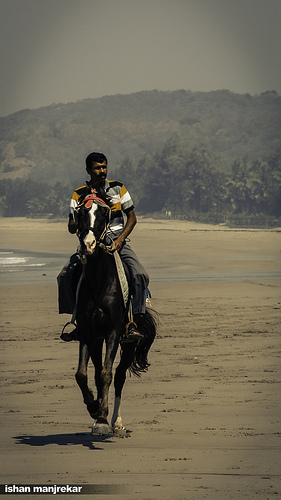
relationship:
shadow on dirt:
[11, 426, 134, 450] [179, 281, 226, 354]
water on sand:
[10, 250, 45, 270] [0, 248, 48, 266]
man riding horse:
[56, 152, 151, 343] [64, 190, 165, 311]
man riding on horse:
[60, 150, 148, 339] [67, 177, 166, 440]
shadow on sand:
[9, 428, 132, 449] [0, 218, 280, 499]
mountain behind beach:
[0, 88, 281, 229] [0, 217, 280, 499]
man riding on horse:
[60, 150, 148, 339] [72, 178, 155, 436]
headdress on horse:
[76, 193, 110, 213] [55, 189, 156, 439]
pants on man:
[102, 230, 151, 314] [51, 155, 160, 350]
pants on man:
[46, 243, 77, 324] [51, 155, 160, 350]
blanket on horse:
[108, 238, 131, 308] [50, 196, 163, 442]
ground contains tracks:
[175, 40, 220, 62] [112, 360, 225, 439]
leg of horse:
[94, 319, 125, 430] [61, 180, 161, 442]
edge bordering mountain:
[2, 212, 272, 229] [0, 88, 281, 229]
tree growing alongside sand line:
[159, 130, 181, 163] [1, 217, 272, 280]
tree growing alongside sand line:
[230, 155, 243, 180] [1, 217, 272, 280]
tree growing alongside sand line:
[189, 140, 211, 177] [1, 217, 272, 280]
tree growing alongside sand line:
[118, 152, 133, 177] [1, 217, 272, 280]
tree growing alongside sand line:
[161, 153, 186, 192] [1, 217, 272, 280]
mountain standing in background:
[0, 85, 272, 217] [2, 86, 272, 223]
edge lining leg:
[96, 414, 107, 419] [75, 345, 117, 434]